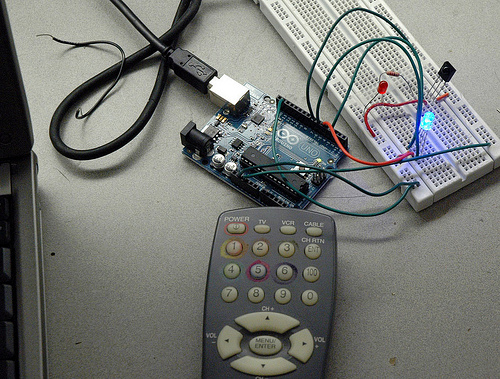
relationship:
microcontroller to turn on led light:
[176, 79, 348, 209] [416, 109, 436, 131]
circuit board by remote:
[254, 0, 498, 215] [198, 206, 340, 376]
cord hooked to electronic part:
[62, 50, 198, 207] [241, 105, 461, 214]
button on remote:
[307, 224, 321, 236] [208, 209, 329, 379]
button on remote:
[279, 223, 296, 238] [201, 195, 345, 379]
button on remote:
[252, 219, 272, 236] [202, 198, 332, 379]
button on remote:
[305, 245, 324, 256] [201, 195, 345, 379]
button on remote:
[276, 244, 294, 260] [194, 217, 331, 379]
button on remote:
[253, 242, 272, 253] [208, 209, 329, 379]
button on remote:
[217, 242, 244, 260] [208, 209, 329, 379]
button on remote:
[269, 264, 289, 284] [208, 209, 329, 379]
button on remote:
[236, 259, 264, 283] [190, 209, 336, 379]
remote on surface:
[200, 205, 338, 379] [155, 232, 209, 372]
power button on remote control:
[222, 214, 249, 234] [200, 205, 326, 379]